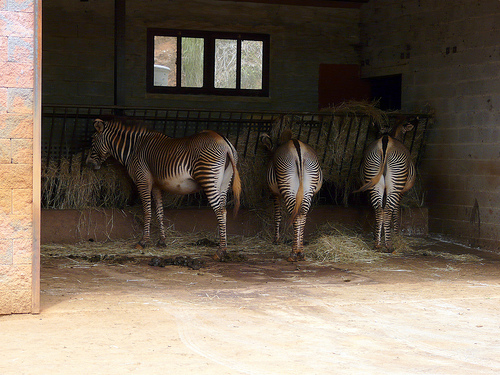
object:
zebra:
[86, 119, 244, 255]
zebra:
[263, 132, 323, 265]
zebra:
[356, 128, 416, 251]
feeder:
[45, 113, 434, 207]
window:
[147, 26, 269, 96]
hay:
[311, 227, 377, 264]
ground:
[0, 237, 499, 374]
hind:
[275, 140, 322, 197]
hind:
[203, 130, 238, 190]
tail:
[353, 138, 390, 193]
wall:
[368, 0, 498, 263]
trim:
[34, 1, 42, 314]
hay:
[318, 106, 374, 196]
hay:
[223, 132, 272, 207]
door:
[318, 75, 361, 112]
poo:
[150, 254, 204, 270]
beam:
[114, 3, 125, 118]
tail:
[228, 151, 242, 220]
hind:
[363, 138, 409, 198]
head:
[85, 118, 114, 171]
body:
[150, 136, 201, 194]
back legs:
[289, 196, 311, 251]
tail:
[284, 157, 306, 232]